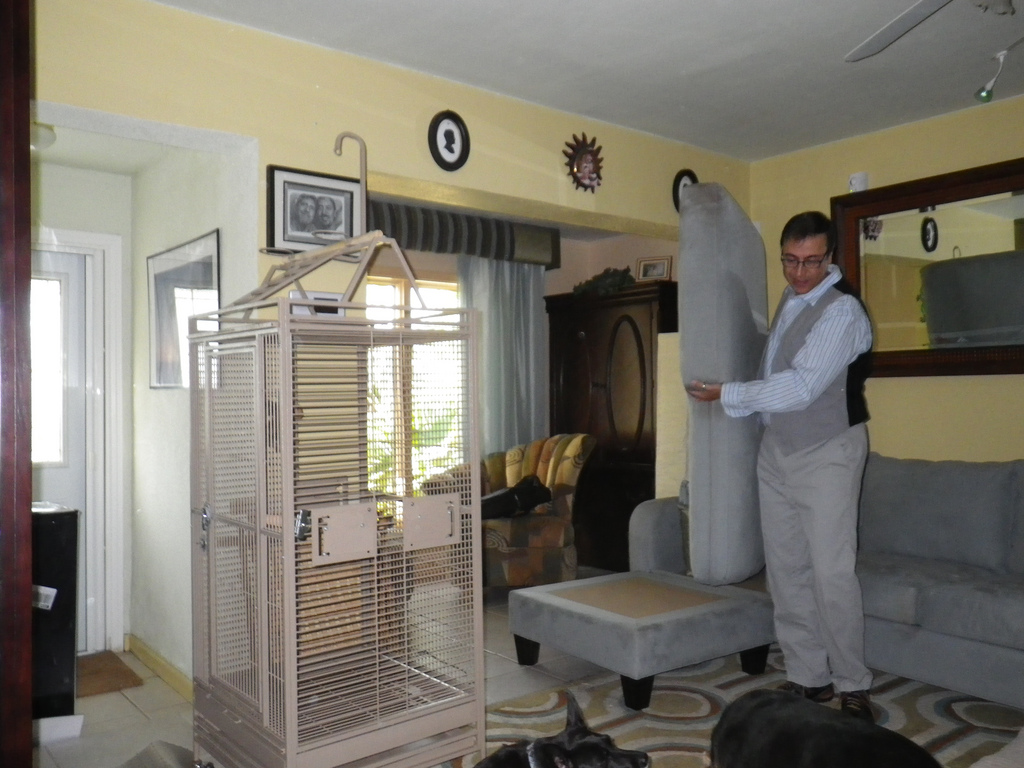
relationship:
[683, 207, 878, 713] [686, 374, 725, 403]
man has hand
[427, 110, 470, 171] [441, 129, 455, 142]
frame has head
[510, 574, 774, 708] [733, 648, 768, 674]
grey ottoman with black leg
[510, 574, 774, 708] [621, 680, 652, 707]
grey ottoman with black leg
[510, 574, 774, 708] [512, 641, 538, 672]
grey ottoman with black leg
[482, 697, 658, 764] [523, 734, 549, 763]
black dog with collar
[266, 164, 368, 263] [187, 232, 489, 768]
frame above bird cage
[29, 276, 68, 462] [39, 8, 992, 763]
window on building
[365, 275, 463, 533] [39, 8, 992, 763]
window on building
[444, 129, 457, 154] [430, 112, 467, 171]
head in frame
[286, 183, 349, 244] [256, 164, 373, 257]
picture in frame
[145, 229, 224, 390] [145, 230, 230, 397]
frame in frame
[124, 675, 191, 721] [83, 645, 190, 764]
tile in floor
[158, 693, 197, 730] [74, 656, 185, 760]
tile in floor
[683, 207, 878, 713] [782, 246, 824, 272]
man wearing glasses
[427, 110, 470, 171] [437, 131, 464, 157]
frame of head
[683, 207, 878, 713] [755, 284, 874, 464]
man has grey vest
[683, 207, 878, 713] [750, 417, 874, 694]
man wearing pants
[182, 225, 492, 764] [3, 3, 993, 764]
bird cage standing inside room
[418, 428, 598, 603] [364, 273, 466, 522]
chair sitting in front of window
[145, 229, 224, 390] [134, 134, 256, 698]
frame hanging on wall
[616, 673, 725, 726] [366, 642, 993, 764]
circle decorating rug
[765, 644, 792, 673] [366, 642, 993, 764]
circle decorating rug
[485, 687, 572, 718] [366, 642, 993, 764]
circle decorating rug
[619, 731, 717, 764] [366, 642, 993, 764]
circle decorating rug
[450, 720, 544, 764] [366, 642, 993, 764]
circle decorating rug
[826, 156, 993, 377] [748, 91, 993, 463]
mirror hanging on wall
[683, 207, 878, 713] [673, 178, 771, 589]
man holding cushion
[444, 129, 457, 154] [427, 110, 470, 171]
head painted in frame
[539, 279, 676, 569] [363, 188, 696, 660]
armoir standing inside room